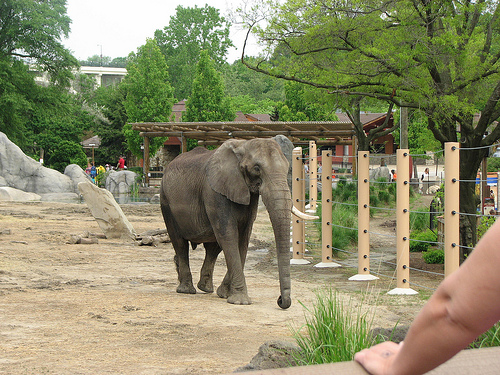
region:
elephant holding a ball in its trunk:
[153, 130, 308, 312]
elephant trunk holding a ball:
[263, 206, 301, 328]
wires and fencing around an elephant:
[348, 140, 418, 297]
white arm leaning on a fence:
[343, 215, 488, 360]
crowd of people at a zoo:
[79, 148, 134, 185]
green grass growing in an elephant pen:
[282, 287, 367, 364]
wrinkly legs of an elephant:
[165, 254, 259, 317]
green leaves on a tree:
[231, 10, 484, 95]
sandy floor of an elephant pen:
[44, 292, 198, 346]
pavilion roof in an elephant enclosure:
[126, 104, 368, 145]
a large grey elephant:
[160, 134, 293, 307]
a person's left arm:
[352, 218, 498, 373]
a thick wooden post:
[357, 151, 369, 281]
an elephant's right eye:
[250, 163, 265, 178]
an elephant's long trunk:
[259, 183, 294, 309]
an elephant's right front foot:
[226, 288, 252, 305]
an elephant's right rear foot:
[176, 281, 195, 293]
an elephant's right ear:
[205, 138, 252, 206]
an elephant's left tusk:
[292, 203, 320, 222]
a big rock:
[73, 182, 135, 244]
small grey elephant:
[157, 129, 302, 302]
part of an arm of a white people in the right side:
[356, 204, 498, 373]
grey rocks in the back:
[0, 128, 135, 216]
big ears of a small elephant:
[208, 130, 301, 206]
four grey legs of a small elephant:
[168, 190, 269, 305]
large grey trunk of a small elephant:
[255, 173, 297, 315]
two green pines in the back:
[128, 31, 228, 181]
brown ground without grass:
[3, 193, 415, 372]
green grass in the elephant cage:
[291, 290, 376, 362]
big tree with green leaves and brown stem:
[258, 5, 499, 262]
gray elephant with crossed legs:
[205, 220, 269, 312]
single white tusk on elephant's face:
[274, 185, 326, 234]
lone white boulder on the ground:
[65, 165, 152, 251]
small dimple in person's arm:
[425, 275, 472, 321]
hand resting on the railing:
[345, 325, 427, 363]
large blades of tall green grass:
[293, 277, 378, 339]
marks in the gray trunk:
[269, 254, 297, 294]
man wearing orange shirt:
[105, 140, 127, 176]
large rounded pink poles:
[338, 143, 389, 296]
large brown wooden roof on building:
[110, 90, 379, 163]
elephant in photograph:
[128, 82, 330, 322]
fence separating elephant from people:
[248, 95, 498, 307]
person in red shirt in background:
[112, 154, 133, 175]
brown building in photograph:
[120, 117, 370, 188]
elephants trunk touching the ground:
[244, 178, 342, 346]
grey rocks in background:
[2, 135, 143, 266]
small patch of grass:
[245, 302, 407, 366]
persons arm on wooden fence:
[350, 161, 498, 361]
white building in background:
[47, 54, 169, 119]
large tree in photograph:
[252, 7, 493, 287]